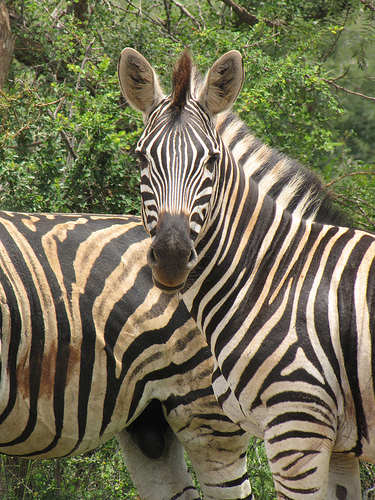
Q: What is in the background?
A: Trees.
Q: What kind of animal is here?
A: Zebra.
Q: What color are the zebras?
A: Black and white.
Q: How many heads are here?
A: One.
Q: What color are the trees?
A: Green.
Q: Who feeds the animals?
A: Zookeeper.